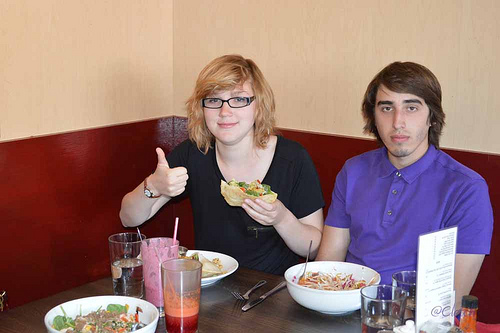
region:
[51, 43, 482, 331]
a couple in a restaurant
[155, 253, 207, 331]
a glass of juice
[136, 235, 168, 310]
a glass of milkshake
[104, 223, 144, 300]
a glass of water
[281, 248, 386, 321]
a bowl of salad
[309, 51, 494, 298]
man wears purple shirt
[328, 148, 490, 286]
purple shirt has buttons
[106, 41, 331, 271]
woman holds a taco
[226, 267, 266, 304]
a fork color silver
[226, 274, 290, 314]
a knife next a fork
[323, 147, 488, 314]
a purple short selves shirt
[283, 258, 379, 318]
a bowl of pasta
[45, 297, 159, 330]
a bowl of salad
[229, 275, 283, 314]
a knife and fork on the table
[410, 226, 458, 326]
a white menu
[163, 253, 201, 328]
a red drink in a glass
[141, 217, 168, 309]
a pink drink in a glass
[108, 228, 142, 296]
a glass of water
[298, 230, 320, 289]
a fork in a bowl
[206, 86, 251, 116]
a pair of black framed glasses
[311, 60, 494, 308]
A man in a purple shirt.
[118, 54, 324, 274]
A girl wearing glasses.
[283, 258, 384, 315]
A white colored bowl.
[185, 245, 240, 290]
A white dinner plate.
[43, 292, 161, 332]
A large white bowl.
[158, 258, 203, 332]
A glass of red liquid.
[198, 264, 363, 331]
A brown table top.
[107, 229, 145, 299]
A clear drinking glass.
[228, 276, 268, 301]
A silver eating fork.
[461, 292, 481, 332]
Top of a condiment bottle.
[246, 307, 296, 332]
a wooden table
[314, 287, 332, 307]
a white bowl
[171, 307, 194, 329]
red liquid in the glass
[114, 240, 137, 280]
a glass of water on the table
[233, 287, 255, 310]
utensils on the table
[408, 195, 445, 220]
man is wearing a blue shirt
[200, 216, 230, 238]
women is wearing a black shirt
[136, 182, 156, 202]
a watch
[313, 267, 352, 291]
food in the bowl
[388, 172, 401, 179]
buttons on the shirt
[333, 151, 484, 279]
purple short sleeve polo shirt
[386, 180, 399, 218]
clear buttons on polo shirt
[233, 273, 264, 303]
shiny silver fork on table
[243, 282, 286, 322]
shiny silver knife on table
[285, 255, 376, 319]
round white bowl of food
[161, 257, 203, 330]
tall glass with red drink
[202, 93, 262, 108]
black framed glasses on woman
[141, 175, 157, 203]
gold watch on womans wrist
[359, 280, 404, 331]
tall clear glass on table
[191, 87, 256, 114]
a young woman wearing eyeglasses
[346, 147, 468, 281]
a young man wearing a purple shirt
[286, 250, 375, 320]
a white bowl with a fork in it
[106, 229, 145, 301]
a clear drinking glass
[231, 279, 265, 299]
a silver fork on a table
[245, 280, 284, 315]
a silver knife on a table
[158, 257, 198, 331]
a drinking glass with red liquid in it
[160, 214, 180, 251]
a plastic straw in a glass